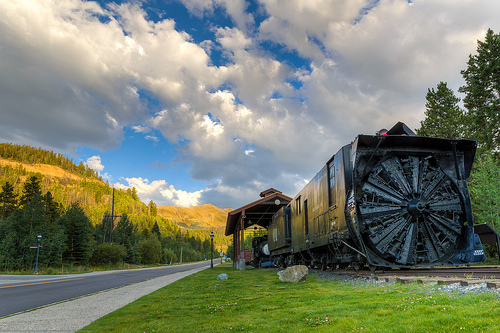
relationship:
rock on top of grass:
[273, 254, 317, 292] [254, 288, 334, 312]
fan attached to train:
[358, 146, 475, 269] [244, 130, 481, 270]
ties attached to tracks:
[349, 269, 490, 289] [276, 253, 492, 286]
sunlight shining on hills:
[9, 145, 215, 232] [8, 145, 213, 249]